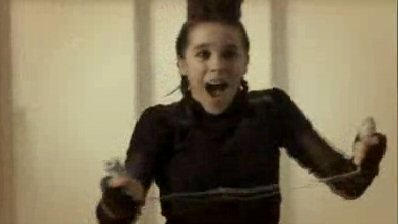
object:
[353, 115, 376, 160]
wii remote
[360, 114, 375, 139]
pole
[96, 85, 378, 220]
shirt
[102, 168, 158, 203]
hand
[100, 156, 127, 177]
pole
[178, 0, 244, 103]
head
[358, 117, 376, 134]
controller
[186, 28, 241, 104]
face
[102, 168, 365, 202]
string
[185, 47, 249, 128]
pig tails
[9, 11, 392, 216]
wall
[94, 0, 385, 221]
girl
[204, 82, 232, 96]
mouth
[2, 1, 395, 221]
room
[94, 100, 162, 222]
arm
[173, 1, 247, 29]
hair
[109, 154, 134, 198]
wii controller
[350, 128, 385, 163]
hand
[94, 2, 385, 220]
woman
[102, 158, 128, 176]
controller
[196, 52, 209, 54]
eye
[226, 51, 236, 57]
eye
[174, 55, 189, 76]
ear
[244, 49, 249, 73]
ear